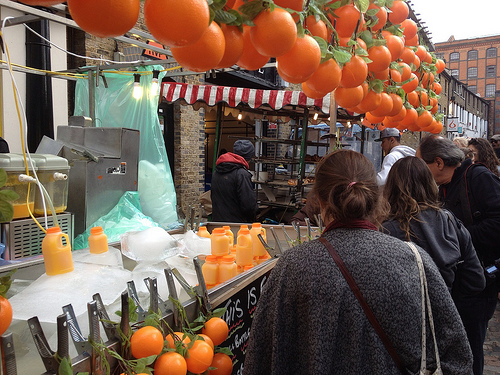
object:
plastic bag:
[70, 59, 181, 232]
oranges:
[140, 0, 210, 48]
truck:
[1, 199, 331, 368]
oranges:
[277, 26, 324, 85]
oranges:
[200, 316, 230, 346]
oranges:
[398, 17, 418, 41]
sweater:
[239, 227, 473, 372]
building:
[0, 0, 499, 261]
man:
[210, 139, 259, 224]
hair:
[381, 154, 441, 240]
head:
[312, 149, 380, 224]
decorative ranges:
[10, 0, 447, 136]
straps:
[422, 264, 441, 367]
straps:
[405, 242, 427, 373]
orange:
[251, 5, 297, 57]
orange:
[279, 34, 320, 79]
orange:
[143, 0, 211, 49]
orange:
[202, 317, 229, 347]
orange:
[129, 325, 165, 360]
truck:
[1, 220, 327, 374]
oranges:
[66, 0, 138, 38]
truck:
[3, 3, 499, 367]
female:
[242, 149, 476, 375]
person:
[467, 137, 499, 178]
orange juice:
[40, 225, 72, 277]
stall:
[1, 0, 445, 374]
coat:
[209, 152, 261, 223]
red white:
[157, 79, 332, 114]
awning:
[160, 81, 331, 116]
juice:
[7, 198, 34, 222]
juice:
[34, 197, 68, 216]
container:
[1, 152, 37, 220]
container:
[12, 152, 71, 214]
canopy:
[153, 67, 346, 112]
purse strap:
[318, 234, 410, 374]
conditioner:
[38, 51, 281, 123]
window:
[0, 1, 86, 159]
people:
[281, 148, 498, 373]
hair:
[309, 148, 390, 226]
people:
[379, 155, 486, 297]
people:
[413, 134, 497, 374]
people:
[371, 126, 415, 185]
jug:
[236, 228, 254, 267]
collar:
[315, 218, 379, 235]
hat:
[231, 139, 255, 161]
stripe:
[181, 78, 245, 107]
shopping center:
[0, 0, 451, 375]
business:
[0, 0, 500, 374]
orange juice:
[211, 229, 230, 257]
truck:
[8, 131, 299, 372]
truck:
[40, 144, 278, 343]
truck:
[40, 80, 380, 224]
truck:
[94, 21, 403, 187]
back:
[287, 244, 416, 375]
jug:
[40, 224, 73, 276]